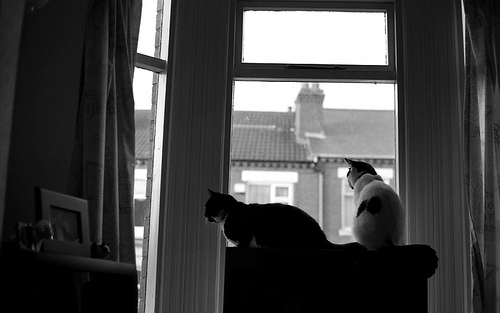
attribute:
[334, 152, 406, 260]
cat — white, laying, black, standing, sitting, spotted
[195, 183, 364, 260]
cat — looking, black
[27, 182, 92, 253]
picture — framed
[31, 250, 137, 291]
shelf — black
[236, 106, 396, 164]
roof — tiled, slanted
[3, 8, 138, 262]
curtain — open, cloth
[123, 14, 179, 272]
window — white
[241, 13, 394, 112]
sky — overcast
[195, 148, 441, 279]
cats — sitting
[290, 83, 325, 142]
chimney — bricks, tall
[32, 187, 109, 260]
frame — wooden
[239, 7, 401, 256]
window — open, large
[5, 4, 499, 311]
photo — indoors